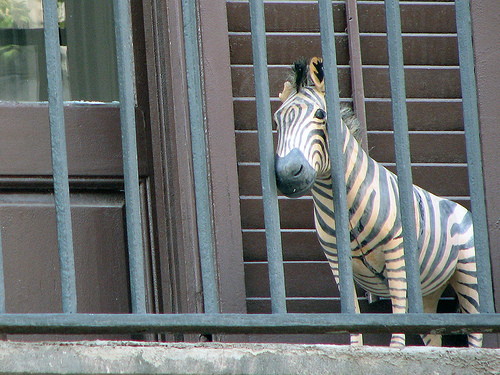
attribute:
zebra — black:
[261, 59, 484, 329]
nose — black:
[269, 148, 322, 197]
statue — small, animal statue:
[235, 80, 409, 284]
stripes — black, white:
[346, 146, 364, 194]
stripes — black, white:
[349, 155, 376, 220]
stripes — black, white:
[356, 166, 391, 254]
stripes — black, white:
[409, 183, 427, 249]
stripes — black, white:
[419, 190, 436, 281]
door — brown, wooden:
[0, 4, 180, 344]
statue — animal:
[266, 54, 468, 304]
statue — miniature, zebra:
[274, 62, 484, 345]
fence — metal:
[1, 0, 496, 335]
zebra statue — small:
[262, 54, 495, 354]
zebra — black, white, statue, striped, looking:
[272, 52, 492, 361]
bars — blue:
[6, 9, 458, 325]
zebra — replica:
[181, 86, 446, 247]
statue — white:
[228, 45, 496, 352]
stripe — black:
[366, 166, 407, 246]